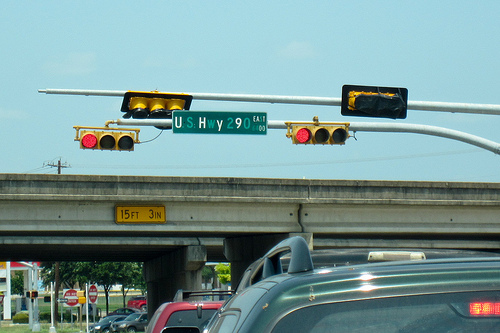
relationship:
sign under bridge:
[64, 288, 95, 303] [0, 173, 500, 238]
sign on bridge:
[113, 205, 167, 221] [0, 173, 500, 238]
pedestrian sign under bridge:
[26, 291, 39, 298] [0, 173, 500, 238]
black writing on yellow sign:
[118, 211, 141, 222] [113, 205, 167, 221]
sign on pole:
[172, 112, 267, 133] [117, 117, 498, 150]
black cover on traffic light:
[356, 97, 405, 110] [340, 83, 410, 117]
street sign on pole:
[172, 112, 267, 133] [117, 117, 498, 150]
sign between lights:
[172, 112, 267, 133] [71, 116, 348, 153]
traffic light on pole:
[79, 130, 138, 152] [117, 117, 498, 150]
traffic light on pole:
[340, 83, 410, 117] [40, 84, 496, 116]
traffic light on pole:
[291, 124, 349, 143] [117, 117, 498, 150]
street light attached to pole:
[122, 95, 187, 112] [40, 84, 496, 116]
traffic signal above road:
[46, 87, 459, 158] [9, 301, 498, 332]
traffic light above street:
[79, 130, 138, 152] [9, 301, 498, 332]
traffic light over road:
[79, 130, 138, 152] [9, 301, 498, 332]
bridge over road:
[0, 173, 500, 238] [9, 301, 498, 332]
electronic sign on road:
[26, 291, 39, 298] [9, 301, 498, 332]